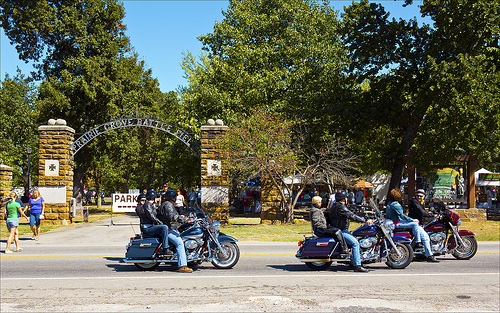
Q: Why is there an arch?
A: For entryway.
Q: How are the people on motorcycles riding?
A: Two per cycle.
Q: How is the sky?
A: Clear and blue.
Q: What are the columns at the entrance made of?
A: Bricks.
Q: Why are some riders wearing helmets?
A: Safety.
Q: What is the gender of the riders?
A: Male and female.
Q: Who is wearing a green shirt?
A: Woman on left.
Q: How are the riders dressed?
A: Leather jackets and blue jeans.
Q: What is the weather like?
A: The sky is clear.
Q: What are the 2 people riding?
A: Motorcycle.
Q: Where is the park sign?
A: Between 2 columns.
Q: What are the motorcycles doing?
A: Riding together.